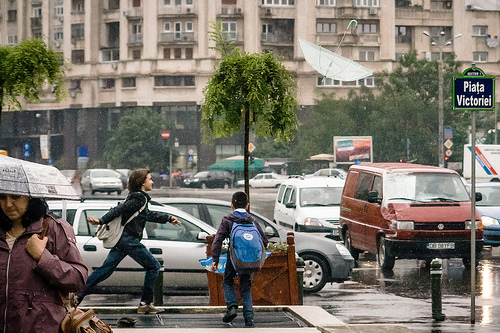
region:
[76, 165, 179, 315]
a person running in street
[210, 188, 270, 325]
a child crossing street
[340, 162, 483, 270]
a red van in street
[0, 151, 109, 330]
a woman with umbrella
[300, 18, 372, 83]
an umbrella flying in air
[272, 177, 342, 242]
a white van in street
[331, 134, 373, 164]
a billboard in distance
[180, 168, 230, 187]
a parked black car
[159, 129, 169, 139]
a red do not enter sign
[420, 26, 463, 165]
an overhead street light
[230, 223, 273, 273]
person wearing a backpack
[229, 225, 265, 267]
a blue and grey backpack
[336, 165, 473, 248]
a red van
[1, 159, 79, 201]
an umbrella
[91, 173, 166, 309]
a person is running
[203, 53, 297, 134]
a green plant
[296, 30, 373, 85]
an umbrella in the sky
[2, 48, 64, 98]
the leaves are green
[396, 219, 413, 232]
headlight on the van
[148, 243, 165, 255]
black handle on the car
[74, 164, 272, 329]
Two children on the sidewalk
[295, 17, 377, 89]
An unbrella in the wind being blown away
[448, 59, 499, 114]
Black sign with white letters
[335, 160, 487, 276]
Brown van driving down the road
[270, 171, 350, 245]
White vehicle following the brown van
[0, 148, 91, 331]
Woman to the left of the children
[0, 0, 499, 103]
Large beige building behind the children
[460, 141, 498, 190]
Back of a white delivery van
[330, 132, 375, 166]
Billboard behind the brown van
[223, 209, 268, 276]
Blue backpack on the little boy's back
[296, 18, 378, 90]
An upside down umbrella in the air.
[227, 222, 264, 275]
A blue and black backpack.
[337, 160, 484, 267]
A dark red van that has been wrecked.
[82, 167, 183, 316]
A boy that is walking.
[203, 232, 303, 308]
A wooden planter.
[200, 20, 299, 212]
A tree in the middle of the city.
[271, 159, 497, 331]
A busy city street.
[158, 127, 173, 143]
A red and white round sign.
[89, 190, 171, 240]
A dark colored jacket.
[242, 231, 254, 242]
A white emblem on a backpack.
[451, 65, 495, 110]
green and blue street sign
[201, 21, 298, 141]
small green tree growing in large planter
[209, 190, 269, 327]
young boy wearing blue backpack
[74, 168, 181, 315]
boy wearing white backpack running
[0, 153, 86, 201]
white and patterned rain umbrella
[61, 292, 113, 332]
woman's brown purse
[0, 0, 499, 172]
large building across the street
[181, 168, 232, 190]
black SUV parked across the street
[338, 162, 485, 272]
big red van driving down street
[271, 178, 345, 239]
white van driving down street